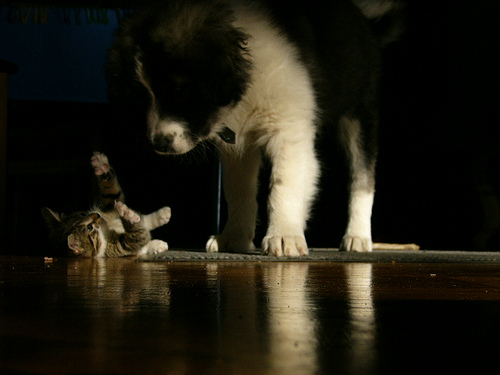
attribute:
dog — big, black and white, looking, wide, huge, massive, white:
[114, 10, 461, 250]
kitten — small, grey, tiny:
[41, 137, 157, 273]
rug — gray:
[135, 220, 496, 274]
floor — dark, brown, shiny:
[3, 245, 499, 367]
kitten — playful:
[41, 169, 202, 282]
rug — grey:
[183, 246, 450, 273]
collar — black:
[204, 119, 284, 167]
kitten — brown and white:
[0, 162, 221, 267]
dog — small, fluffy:
[152, 19, 441, 285]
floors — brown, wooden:
[0, 247, 484, 373]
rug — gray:
[149, 248, 483, 263]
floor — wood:
[2, 249, 481, 372]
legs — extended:
[87, 145, 151, 259]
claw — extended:
[105, 194, 144, 226]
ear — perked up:
[42, 205, 68, 229]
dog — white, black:
[125, 1, 388, 260]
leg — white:
[332, 101, 380, 258]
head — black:
[132, 1, 254, 162]